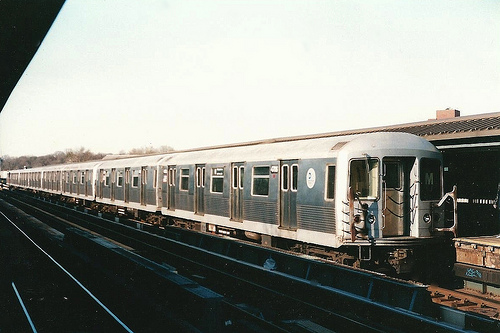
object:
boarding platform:
[437, 200, 498, 297]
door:
[378, 155, 407, 238]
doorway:
[380, 155, 417, 239]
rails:
[0, 183, 499, 333]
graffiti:
[461, 267, 483, 281]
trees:
[3, 155, 26, 172]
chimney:
[433, 103, 465, 124]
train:
[0, 130, 466, 263]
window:
[249, 165, 272, 199]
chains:
[339, 199, 356, 209]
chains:
[382, 178, 420, 195]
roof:
[147, 109, 500, 153]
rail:
[3, 213, 145, 332]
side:
[0, 134, 455, 267]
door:
[277, 157, 299, 234]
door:
[227, 159, 248, 222]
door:
[192, 162, 207, 217]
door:
[167, 165, 176, 212]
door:
[138, 166, 147, 207]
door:
[124, 167, 131, 203]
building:
[92, 100, 496, 308]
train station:
[134, 104, 497, 278]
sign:
[303, 163, 318, 192]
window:
[347, 156, 380, 201]